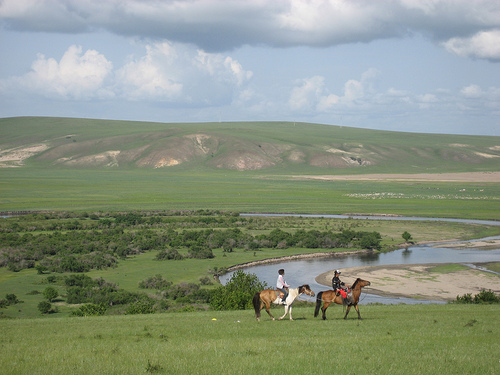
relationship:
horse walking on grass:
[251, 283, 316, 321] [0, 302, 499, 371]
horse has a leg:
[316, 274, 374, 317] [355, 307, 363, 318]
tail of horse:
[248, 282, 275, 328] [239, 260, 314, 333]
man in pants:
[330, 268, 351, 306] [329, 276, 353, 309]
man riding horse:
[330, 268, 351, 306] [310, 259, 378, 339]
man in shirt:
[264, 245, 302, 315] [270, 266, 294, 287]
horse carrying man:
[313, 277, 372, 320] [264, 240, 304, 326]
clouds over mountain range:
[64, 25, 208, 74] [0, 117, 499, 171]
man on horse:
[275, 269, 293, 304] [237, 236, 328, 359]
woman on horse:
[259, 262, 291, 286] [246, 284, 308, 324]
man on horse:
[320, 254, 355, 294] [308, 283, 401, 326]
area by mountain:
[43, 156, 451, 229] [36, 114, 460, 184]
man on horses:
[275, 269, 293, 304] [243, 284, 374, 315]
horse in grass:
[251, 280, 316, 321] [216, 314, 380, 370]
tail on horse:
[311, 288, 323, 320] [307, 277, 371, 321]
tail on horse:
[252, 287, 262, 318] [244, 282, 317, 322]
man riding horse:
[275, 269, 293, 304] [251, 283, 316, 321]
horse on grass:
[251, 283, 316, 321] [178, 321, 348, 372]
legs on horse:
[340, 301, 364, 321] [313, 276, 372, 319]